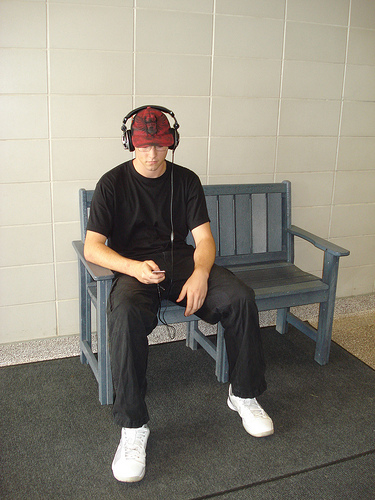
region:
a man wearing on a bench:
[14, 67, 364, 429]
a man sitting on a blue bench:
[35, 90, 372, 415]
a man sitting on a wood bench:
[40, 105, 372, 439]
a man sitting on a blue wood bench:
[41, 93, 367, 476]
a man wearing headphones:
[59, 66, 270, 239]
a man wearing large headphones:
[76, 81, 221, 233]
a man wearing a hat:
[102, 76, 222, 213]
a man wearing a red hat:
[81, 67, 202, 183]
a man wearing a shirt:
[40, 93, 246, 277]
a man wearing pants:
[79, 108, 299, 420]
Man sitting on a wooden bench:
[72, 99, 310, 483]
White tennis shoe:
[105, 421, 157, 484]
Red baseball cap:
[130, 96, 177, 157]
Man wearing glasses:
[130, 139, 173, 158]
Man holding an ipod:
[136, 254, 191, 339]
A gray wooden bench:
[254, 176, 352, 294]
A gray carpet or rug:
[16, 392, 82, 473]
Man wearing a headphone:
[112, 97, 188, 154]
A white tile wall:
[30, 91, 93, 163]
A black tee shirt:
[93, 164, 206, 237]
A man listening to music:
[81, 99, 277, 484]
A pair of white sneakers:
[110, 382, 275, 484]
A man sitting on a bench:
[71, 104, 352, 484]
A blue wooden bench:
[72, 179, 353, 406]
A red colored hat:
[127, 103, 179, 152]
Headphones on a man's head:
[117, 101, 184, 154]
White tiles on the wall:
[0, 1, 371, 342]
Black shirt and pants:
[84, 159, 267, 429]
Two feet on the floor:
[107, 383, 277, 485]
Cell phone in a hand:
[135, 252, 169, 288]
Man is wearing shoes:
[96, 378, 276, 486]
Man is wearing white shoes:
[101, 381, 281, 487]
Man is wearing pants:
[103, 255, 272, 431]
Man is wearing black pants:
[102, 244, 273, 428]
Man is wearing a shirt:
[84, 154, 211, 253]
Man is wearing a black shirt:
[81, 155, 212, 257]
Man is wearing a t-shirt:
[86, 156, 214, 262]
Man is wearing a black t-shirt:
[85, 157, 213, 259]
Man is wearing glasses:
[131, 139, 177, 152]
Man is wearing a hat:
[129, 105, 177, 147]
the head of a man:
[126, 103, 183, 173]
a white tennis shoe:
[105, 419, 153, 485]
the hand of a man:
[130, 254, 169, 288]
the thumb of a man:
[173, 283, 189, 304]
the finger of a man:
[181, 288, 194, 319]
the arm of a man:
[76, 172, 135, 279]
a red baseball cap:
[126, 104, 173, 152]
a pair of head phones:
[116, 103, 182, 155]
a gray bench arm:
[69, 236, 116, 284]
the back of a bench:
[79, 178, 298, 283]